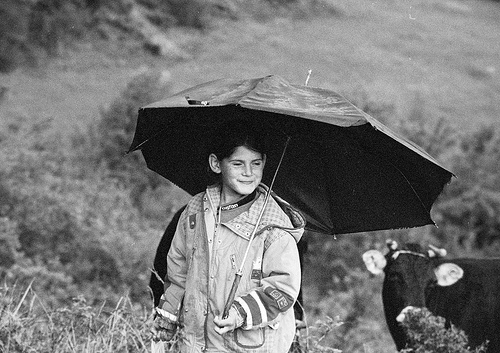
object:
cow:
[354, 237, 491, 346]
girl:
[157, 132, 310, 350]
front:
[162, 184, 301, 353]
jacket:
[156, 188, 309, 350]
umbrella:
[133, 67, 456, 335]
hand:
[212, 300, 247, 334]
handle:
[220, 272, 241, 318]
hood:
[202, 185, 310, 240]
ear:
[431, 262, 462, 285]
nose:
[392, 302, 431, 329]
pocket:
[233, 325, 270, 350]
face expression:
[222, 149, 270, 192]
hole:
[186, 96, 221, 114]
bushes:
[1, 71, 497, 278]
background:
[2, 2, 499, 243]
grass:
[8, 1, 499, 130]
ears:
[361, 250, 386, 275]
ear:
[208, 153, 221, 173]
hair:
[207, 121, 273, 158]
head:
[358, 238, 464, 327]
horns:
[382, 236, 446, 257]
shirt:
[217, 195, 263, 223]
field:
[2, 3, 498, 263]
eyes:
[388, 274, 401, 281]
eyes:
[230, 163, 242, 169]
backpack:
[291, 217, 309, 317]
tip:
[299, 64, 319, 90]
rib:
[361, 139, 458, 229]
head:
[206, 126, 268, 194]